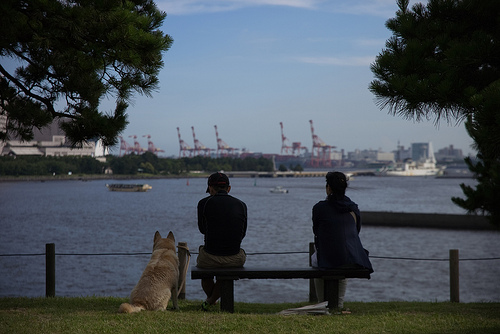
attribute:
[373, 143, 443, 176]
boat — white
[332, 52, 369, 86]
clouds — few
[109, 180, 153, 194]
boat — small, tan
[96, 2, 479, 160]
clouds — white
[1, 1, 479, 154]
sky — blue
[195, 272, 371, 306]
bench — black, small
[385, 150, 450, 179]
ship — large, white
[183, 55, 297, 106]
sky — blue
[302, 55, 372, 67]
clouds — white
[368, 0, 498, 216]
trees — evergreen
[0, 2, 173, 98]
leaves — thick, dark green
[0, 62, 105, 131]
branch — firm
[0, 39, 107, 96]
branch — firm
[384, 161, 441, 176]
boat — white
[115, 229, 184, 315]
dog — light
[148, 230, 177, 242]
ears — perked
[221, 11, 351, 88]
clouds — white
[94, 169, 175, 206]
boat — white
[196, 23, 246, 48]
clouds — white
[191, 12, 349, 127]
sky — blue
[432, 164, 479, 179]
boat — white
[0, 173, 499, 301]
water — in front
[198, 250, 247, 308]
pants — khaki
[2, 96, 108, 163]
boat — white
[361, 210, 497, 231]
boat — white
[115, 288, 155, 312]
tail — Fluffy, yellow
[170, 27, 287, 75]
sky — blue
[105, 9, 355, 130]
sky — blue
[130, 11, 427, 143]
sky — blue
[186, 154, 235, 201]
cap — dark, baseball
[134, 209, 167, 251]
ear — perked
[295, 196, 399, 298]
jacket — blue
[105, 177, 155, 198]
boat — white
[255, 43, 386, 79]
clouds — white